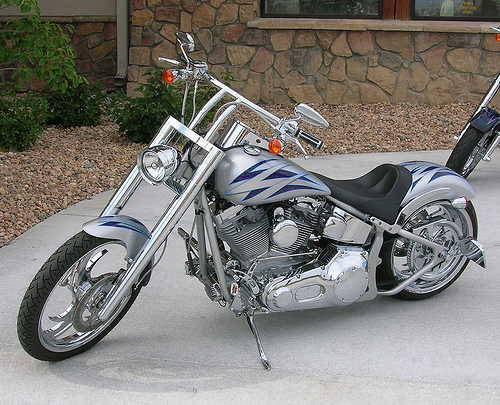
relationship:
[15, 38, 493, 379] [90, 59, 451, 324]
bike has frame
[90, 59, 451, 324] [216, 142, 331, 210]
frame has designs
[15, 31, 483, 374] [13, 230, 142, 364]
bike has wheel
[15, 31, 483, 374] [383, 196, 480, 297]
bike has tire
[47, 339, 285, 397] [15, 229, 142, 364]
shadow from tire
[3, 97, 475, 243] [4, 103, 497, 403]
rocks on ground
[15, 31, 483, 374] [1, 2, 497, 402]
bike in picture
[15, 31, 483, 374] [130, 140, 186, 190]
bike has headlight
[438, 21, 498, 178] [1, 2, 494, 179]
bike in background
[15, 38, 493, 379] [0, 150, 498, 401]
bike in driveway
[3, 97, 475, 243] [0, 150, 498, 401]
rocks next to driveway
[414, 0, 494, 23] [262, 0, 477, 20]
sign in window